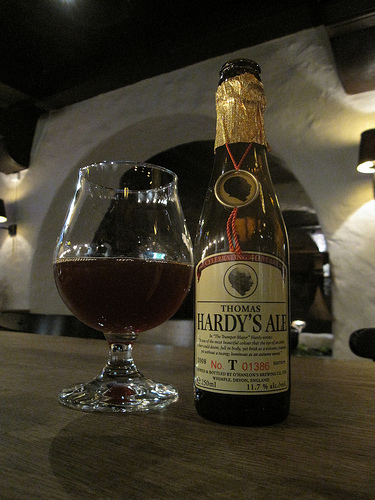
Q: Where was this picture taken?
A: At a bar.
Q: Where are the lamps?
A: On the white wall.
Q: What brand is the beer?
A: Thomas Hardy's Ale.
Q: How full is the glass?
A: Half full.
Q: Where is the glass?
A: To the left of the bottle.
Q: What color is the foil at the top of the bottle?
A: Gold.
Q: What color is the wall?
A: White.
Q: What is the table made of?
A: Wood.